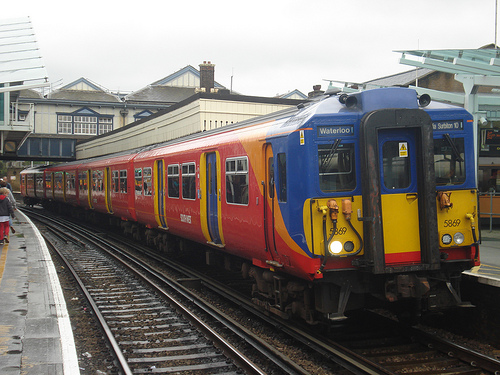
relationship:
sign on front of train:
[315, 123, 355, 137] [19, 87, 486, 328]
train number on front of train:
[443, 216, 464, 227] [19, 87, 486, 328]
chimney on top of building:
[195, 61, 217, 92] [70, 90, 306, 160]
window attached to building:
[54, 104, 112, 135] [0, 62, 308, 160]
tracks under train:
[16, 205, 268, 374] [19, 87, 486, 328]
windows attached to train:
[165, 162, 196, 202] [19, 87, 486, 328]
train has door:
[19, 87, 486, 328] [198, 150, 225, 242]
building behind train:
[70, 90, 306, 160] [19, 87, 486, 328]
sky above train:
[0, 1, 499, 99] [19, 87, 486, 328]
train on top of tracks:
[19, 87, 486, 328] [16, 205, 268, 374]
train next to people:
[19, 87, 486, 328] [0, 177, 17, 246]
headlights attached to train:
[328, 230, 465, 252] [19, 87, 486, 328]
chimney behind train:
[195, 61, 217, 92] [19, 87, 486, 328]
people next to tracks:
[0, 177, 17, 246] [16, 205, 268, 374]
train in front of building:
[19, 87, 486, 328] [70, 90, 306, 160]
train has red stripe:
[19, 87, 486, 328] [263, 126, 311, 136]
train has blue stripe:
[19, 87, 486, 328] [269, 139, 320, 262]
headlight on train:
[323, 239, 343, 255] [12, 71, 488, 309]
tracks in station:
[16, 205, 268, 374] [6, 171, 496, 369]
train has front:
[19, 87, 486, 328] [297, 80, 486, 307]